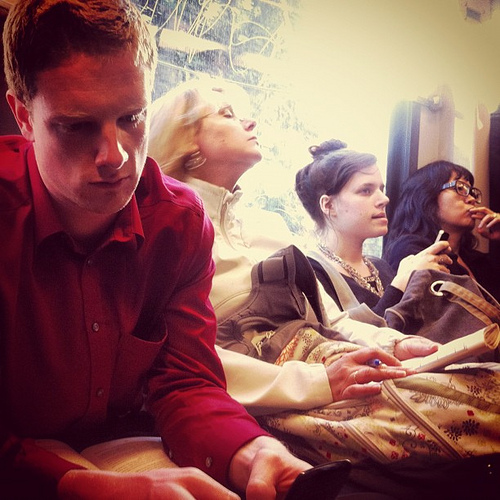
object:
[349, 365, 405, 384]
finger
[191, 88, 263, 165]
face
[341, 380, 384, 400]
finger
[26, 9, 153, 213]
face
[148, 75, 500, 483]
lady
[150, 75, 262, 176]
head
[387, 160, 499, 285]
woman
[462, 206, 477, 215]
mouth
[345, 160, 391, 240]
face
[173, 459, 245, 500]
finger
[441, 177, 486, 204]
glasses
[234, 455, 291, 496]
finger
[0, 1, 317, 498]
person